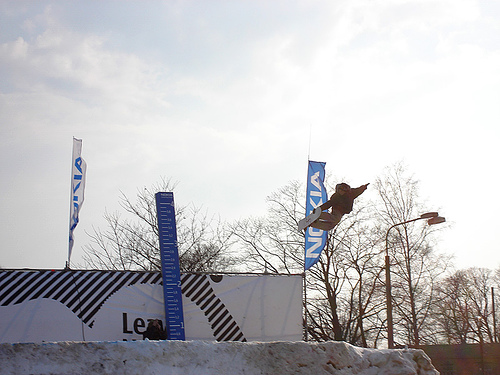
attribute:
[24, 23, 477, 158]
clouds — wispy, white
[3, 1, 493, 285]
sky — baby blue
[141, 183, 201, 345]
board — blue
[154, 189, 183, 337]
ruler — large, blue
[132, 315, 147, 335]
letter e — black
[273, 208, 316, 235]
board — marked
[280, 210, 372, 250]
pants — brown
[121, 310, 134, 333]
letter — black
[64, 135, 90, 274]
banner — white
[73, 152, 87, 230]
letters — blue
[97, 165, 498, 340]
trees — brown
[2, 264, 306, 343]
billboard — zebra stripe, white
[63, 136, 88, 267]
fabric — white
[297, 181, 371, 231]
trick — radical